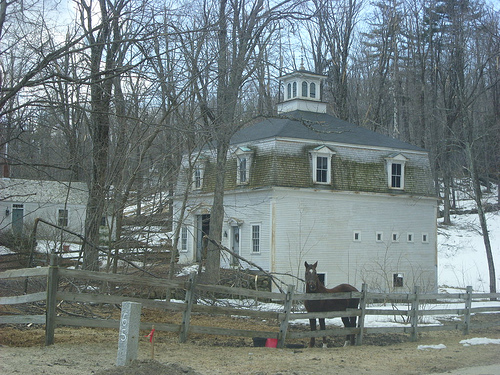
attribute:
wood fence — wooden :
[2, 250, 499, 348]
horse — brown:
[303, 260, 359, 349]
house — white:
[188, 108, 470, 317]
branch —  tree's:
[268, 0, 332, 27]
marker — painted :
[113, 296, 149, 373]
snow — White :
[81, 169, 498, 316]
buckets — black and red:
[251, 335, 277, 349]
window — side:
[301, 138, 337, 191]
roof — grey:
[180, 107, 439, 155]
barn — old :
[172, 57, 463, 344]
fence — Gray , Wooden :
[1, 259, 498, 349]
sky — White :
[0, 12, 489, 129]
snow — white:
[438, 172, 498, 295]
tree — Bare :
[39, 0, 141, 274]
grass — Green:
[304, 350, 364, 366]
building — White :
[1, 169, 93, 248]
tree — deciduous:
[173, 0, 272, 295]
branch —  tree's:
[27, 8, 212, 139]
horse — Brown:
[302, 261, 362, 345]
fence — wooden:
[1, 252, 499, 346]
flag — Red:
[133, 314, 183, 358]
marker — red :
[144, 323, 156, 341]